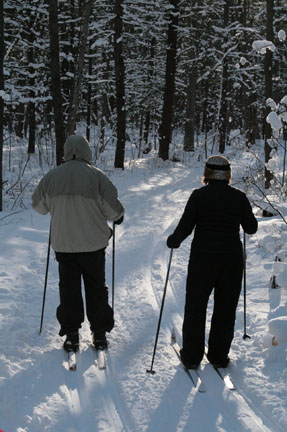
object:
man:
[31, 135, 126, 353]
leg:
[56, 263, 84, 333]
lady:
[166, 155, 258, 369]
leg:
[183, 281, 213, 360]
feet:
[64, 329, 79, 352]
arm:
[99, 171, 125, 220]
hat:
[203, 155, 232, 182]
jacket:
[167, 183, 259, 268]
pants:
[179, 259, 244, 365]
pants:
[56, 251, 115, 336]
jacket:
[32, 133, 125, 262]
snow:
[5, 127, 286, 430]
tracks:
[66, 234, 271, 428]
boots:
[180, 348, 200, 369]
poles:
[151, 246, 174, 370]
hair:
[201, 166, 233, 186]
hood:
[63, 134, 93, 164]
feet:
[180, 349, 200, 369]